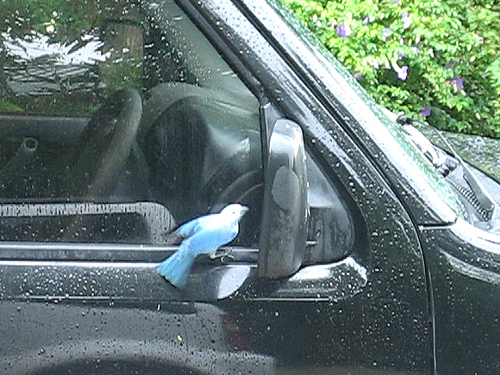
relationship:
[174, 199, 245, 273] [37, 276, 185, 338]
bird on door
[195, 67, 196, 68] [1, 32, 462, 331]
rain on car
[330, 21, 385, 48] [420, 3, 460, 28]
flowers on bushes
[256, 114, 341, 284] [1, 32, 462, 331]
mirror of car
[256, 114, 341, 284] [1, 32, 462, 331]
mirror on car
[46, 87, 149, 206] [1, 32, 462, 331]
steering wheel in car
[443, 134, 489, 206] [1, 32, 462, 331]
windshield wiper on car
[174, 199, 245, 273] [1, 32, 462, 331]
bird on car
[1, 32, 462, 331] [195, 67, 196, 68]
car has rain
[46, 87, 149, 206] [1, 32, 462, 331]
steering wheel of car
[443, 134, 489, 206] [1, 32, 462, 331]
windshield wiper of car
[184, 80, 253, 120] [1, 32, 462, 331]
dashboard of car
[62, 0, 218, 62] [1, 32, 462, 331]
window of car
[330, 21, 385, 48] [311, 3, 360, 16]
flowers on bush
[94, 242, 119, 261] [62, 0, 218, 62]
knob of window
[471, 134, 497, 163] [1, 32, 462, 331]
hood of car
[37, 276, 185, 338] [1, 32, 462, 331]
door of car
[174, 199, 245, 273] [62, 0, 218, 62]
bird on window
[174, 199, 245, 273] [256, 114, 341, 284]
bird on mirror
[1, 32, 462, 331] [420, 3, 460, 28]
car next to bushes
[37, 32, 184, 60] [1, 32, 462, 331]
reflection on car